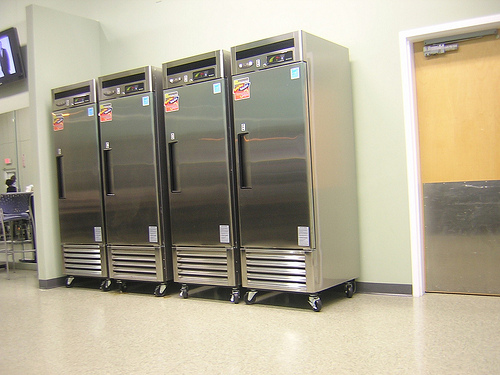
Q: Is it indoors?
A: Yes, it is indoors.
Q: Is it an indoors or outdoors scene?
A: It is indoors.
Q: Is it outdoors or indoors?
A: It is indoors.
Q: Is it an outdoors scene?
A: No, it is indoors.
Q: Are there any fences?
A: No, there are no fences.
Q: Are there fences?
A: No, there are no fences.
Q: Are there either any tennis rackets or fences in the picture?
A: No, there are no fences or tennis rackets.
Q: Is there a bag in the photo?
A: No, there are no bags.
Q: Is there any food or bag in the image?
A: No, there are no bags or food.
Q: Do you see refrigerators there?
A: Yes, there is a refrigerator.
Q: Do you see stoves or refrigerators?
A: Yes, there is a refrigerator.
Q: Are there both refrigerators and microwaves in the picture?
A: No, there is a refrigerator but no microwaves.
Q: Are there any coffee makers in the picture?
A: No, there are no coffee makers.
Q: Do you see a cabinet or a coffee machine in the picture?
A: No, there are no coffee makers or cabinets.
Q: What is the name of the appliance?
A: The appliance is a refrigerator.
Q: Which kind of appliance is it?
A: The appliance is a refrigerator.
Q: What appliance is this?
A: This is a refrigerator.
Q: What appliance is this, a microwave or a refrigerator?
A: This is a refrigerator.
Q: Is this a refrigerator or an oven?
A: This is a refrigerator.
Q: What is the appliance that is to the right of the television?
A: The appliance is a refrigerator.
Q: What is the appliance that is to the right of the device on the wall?
A: The appliance is a refrigerator.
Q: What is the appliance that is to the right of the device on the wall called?
A: The appliance is a refrigerator.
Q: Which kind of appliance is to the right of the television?
A: The appliance is a refrigerator.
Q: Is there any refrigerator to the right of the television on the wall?
A: Yes, there is a refrigerator to the right of the TV.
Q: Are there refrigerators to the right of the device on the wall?
A: Yes, there is a refrigerator to the right of the TV.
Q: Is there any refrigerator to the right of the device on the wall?
A: Yes, there is a refrigerator to the right of the TV.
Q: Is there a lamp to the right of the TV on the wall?
A: No, there is a refrigerator to the right of the TV.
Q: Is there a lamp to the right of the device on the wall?
A: No, there is a refrigerator to the right of the TV.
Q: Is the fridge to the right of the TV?
A: Yes, the fridge is to the right of the TV.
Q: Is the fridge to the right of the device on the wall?
A: Yes, the fridge is to the right of the TV.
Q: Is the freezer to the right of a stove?
A: No, the freezer is to the right of the TV.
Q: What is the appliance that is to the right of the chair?
A: The appliance is a refrigerator.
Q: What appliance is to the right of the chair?
A: The appliance is a refrigerator.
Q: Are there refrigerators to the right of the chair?
A: Yes, there is a refrigerator to the right of the chair.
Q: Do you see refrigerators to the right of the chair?
A: Yes, there is a refrigerator to the right of the chair.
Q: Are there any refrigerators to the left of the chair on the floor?
A: No, the refrigerator is to the right of the chair.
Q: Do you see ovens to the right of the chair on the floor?
A: No, there is a refrigerator to the right of the chair.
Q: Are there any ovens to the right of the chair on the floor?
A: No, there is a refrigerator to the right of the chair.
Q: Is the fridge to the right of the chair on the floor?
A: Yes, the fridge is to the right of the chair.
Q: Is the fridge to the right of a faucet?
A: No, the fridge is to the right of the chair.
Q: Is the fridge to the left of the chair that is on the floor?
A: No, the fridge is to the right of the chair.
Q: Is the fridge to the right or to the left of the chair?
A: The fridge is to the right of the chair.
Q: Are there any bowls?
A: No, there are no bowls.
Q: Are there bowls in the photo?
A: No, there are no bowls.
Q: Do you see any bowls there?
A: No, there are no bowls.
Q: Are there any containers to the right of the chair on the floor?
A: Yes, there is a container to the right of the chair.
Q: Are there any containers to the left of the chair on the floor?
A: No, the container is to the right of the chair.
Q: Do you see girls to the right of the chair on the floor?
A: No, there is a container to the right of the chair.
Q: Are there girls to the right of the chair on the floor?
A: No, there is a container to the right of the chair.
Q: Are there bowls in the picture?
A: No, there are no bowls.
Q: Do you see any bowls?
A: No, there are no bowls.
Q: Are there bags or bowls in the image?
A: No, there are no bowls or bags.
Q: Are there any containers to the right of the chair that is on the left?
A: Yes, there is a container to the right of the chair.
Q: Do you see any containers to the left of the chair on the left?
A: No, the container is to the right of the chair.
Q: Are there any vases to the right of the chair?
A: No, there is a container to the right of the chair.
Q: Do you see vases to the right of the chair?
A: No, there is a container to the right of the chair.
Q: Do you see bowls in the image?
A: No, there are no bowls.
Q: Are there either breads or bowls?
A: No, there are no bowls or breads.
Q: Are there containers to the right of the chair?
A: Yes, there is a container to the right of the chair.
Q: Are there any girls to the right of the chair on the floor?
A: No, there is a container to the right of the chair.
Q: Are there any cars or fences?
A: No, there are no fences or cars.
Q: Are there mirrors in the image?
A: No, there are no mirrors.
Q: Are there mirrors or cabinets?
A: No, there are no mirrors or cabinets.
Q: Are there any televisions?
A: Yes, there is a television.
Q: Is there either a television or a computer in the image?
A: Yes, there is a television.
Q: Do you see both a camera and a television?
A: No, there is a television but no cameras.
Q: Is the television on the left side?
A: Yes, the television is on the left of the image.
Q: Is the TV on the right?
A: No, the TV is on the left of the image.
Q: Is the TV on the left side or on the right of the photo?
A: The TV is on the left of the image.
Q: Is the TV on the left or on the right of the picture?
A: The TV is on the left of the image.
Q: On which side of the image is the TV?
A: The TV is on the left of the image.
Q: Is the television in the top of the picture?
A: Yes, the television is in the top of the image.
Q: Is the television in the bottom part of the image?
A: No, the television is in the top of the image.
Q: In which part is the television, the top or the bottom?
A: The television is in the top of the image.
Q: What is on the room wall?
A: The TV is on the wall.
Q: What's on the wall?
A: The TV is on the wall.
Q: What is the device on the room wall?
A: The device is a television.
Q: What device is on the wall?
A: The device is a television.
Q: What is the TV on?
A: The TV is on the wall.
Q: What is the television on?
A: The TV is on the wall.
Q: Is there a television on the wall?
A: Yes, there is a television on the wall.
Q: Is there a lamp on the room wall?
A: No, there is a television on the wall.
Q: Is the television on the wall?
A: Yes, the television is on the wall.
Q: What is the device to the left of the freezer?
A: The device is a television.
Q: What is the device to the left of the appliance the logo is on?
A: The device is a television.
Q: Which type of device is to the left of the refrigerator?
A: The device is a television.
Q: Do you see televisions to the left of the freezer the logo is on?
A: Yes, there is a television to the left of the refrigerator.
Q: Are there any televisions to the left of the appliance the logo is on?
A: Yes, there is a television to the left of the refrigerator.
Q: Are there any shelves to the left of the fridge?
A: No, there is a television to the left of the fridge.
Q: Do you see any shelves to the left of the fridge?
A: No, there is a television to the left of the fridge.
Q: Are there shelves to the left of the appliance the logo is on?
A: No, there is a television to the left of the fridge.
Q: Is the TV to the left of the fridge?
A: Yes, the TV is to the left of the fridge.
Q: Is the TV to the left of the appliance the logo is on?
A: Yes, the TV is to the left of the fridge.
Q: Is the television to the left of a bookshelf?
A: No, the television is to the left of the fridge.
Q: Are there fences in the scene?
A: No, there are no fences.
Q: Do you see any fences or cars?
A: No, there are no fences or cars.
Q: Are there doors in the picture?
A: Yes, there is a door.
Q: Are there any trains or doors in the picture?
A: Yes, there is a door.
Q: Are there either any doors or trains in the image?
A: Yes, there is a door.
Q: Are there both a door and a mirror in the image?
A: No, there is a door but no mirrors.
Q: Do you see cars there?
A: No, there are no cars.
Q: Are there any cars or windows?
A: No, there are no cars or windows.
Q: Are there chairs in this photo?
A: Yes, there is a chair.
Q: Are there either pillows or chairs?
A: Yes, there is a chair.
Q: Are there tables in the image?
A: No, there are no tables.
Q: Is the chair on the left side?
A: Yes, the chair is on the left of the image.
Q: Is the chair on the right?
A: No, the chair is on the left of the image.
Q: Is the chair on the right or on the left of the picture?
A: The chair is on the left of the image.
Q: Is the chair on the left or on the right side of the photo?
A: The chair is on the left of the image.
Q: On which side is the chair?
A: The chair is on the left of the image.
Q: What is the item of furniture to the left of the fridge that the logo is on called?
A: The piece of furniture is a chair.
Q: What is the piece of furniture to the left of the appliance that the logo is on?
A: The piece of furniture is a chair.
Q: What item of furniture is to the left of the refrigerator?
A: The piece of furniture is a chair.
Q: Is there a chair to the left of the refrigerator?
A: Yes, there is a chair to the left of the refrigerator.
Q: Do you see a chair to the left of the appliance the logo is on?
A: Yes, there is a chair to the left of the refrigerator.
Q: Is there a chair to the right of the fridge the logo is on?
A: No, the chair is to the left of the refrigerator.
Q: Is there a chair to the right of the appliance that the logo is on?
A: No, the chair is to the left of the refrigerator.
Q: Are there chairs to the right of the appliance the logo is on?
A: No, the chair is to the left of the refrigerator.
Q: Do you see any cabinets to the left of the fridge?
A: No, there is a chair to the left of the fridge.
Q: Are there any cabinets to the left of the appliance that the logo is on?
A: No, there is a chair to the left of the fridge.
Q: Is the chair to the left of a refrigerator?
A: Yes, the chair is to the left of a refrigerator.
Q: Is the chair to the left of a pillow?
A: No, the chair is to the left of a refrigerator.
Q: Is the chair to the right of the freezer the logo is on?
A: No, the chair is to the left of the fridge.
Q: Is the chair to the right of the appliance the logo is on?
A: No, the chair is to the left of the fridge.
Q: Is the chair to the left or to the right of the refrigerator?
A: The chair is to the left of the refrigerator.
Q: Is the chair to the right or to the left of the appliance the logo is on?
A: The chair is to the left of the refrigerator.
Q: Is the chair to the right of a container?
A: No, the chair is to the left of a container.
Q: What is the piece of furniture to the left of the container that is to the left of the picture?
A: The piece of furniture is a chair.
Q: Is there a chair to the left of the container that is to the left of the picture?
A: Yes, there is a chair to the left of the container.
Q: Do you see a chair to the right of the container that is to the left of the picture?
A: No, the chair is to the left of the container.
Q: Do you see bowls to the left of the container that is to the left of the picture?
A: No, there is a chair to the left of the container.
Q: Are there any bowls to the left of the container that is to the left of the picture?
A: No, there is a chair to the left of the container.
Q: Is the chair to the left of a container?
A: Yes, the chair is to the left of a container.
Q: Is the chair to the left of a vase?
A: No, the chair is to the left of a container.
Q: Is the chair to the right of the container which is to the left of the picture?
A: No, the chair is to the left of the container.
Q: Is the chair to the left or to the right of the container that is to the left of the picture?
A: The chair is to the left of the container.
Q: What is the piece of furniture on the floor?
A: The piece of furniture is a chair.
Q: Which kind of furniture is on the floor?
A: The piece of furniture is a chair.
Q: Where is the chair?
A: The chair is on the floor.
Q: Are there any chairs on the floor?
A: Yes, there is a chair on the floor.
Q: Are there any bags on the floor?
A: No, there is a chair on the floor.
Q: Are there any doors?
A: Yes, there is a door.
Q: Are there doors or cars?
A: Yes, there is a door.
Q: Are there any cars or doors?
A: Yes, there is a door.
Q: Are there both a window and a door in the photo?
A: No, there is a door but no windows.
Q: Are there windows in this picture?
A: No, there are no windows.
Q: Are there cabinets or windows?
A: No, there are no windows or cabinets.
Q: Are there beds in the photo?
A: No, there are no beds.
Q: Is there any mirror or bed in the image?
A: No, there are no beds or mirrors.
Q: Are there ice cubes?
A: No, there are no ice cubes.